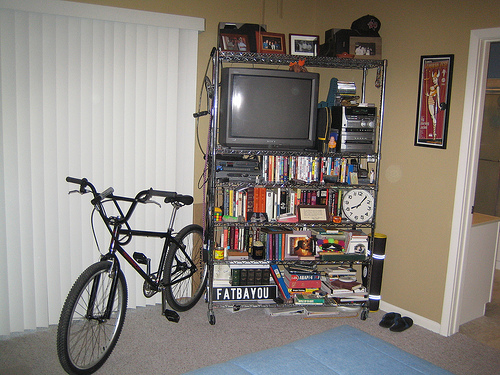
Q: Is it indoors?
A: Yes, it is indoors.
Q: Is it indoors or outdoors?
A: It is indoors.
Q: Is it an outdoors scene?
A: No, it is indoors.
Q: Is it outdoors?
A: No, it is indoors.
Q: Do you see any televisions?
A: Yes, there is a television.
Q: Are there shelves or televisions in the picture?
A: Yes, there is a television.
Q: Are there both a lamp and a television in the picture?
A: No, there is a television but no lamps.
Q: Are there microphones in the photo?
A: No, there are no microphones.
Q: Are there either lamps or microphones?
A: No, there are no microphones or lamps.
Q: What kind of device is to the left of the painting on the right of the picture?
A: The device is a television.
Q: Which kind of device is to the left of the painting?
A: The device is a television.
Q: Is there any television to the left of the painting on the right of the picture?
A: Yes, there is a television to the left of the painting.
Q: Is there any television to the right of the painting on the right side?
A: No, the television is to the left of the painting.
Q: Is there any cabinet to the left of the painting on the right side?
A: No, there is a television to the left of the painting.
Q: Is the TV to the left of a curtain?
A: No, the TV is to the left of the painting.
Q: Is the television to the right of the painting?
A: No, the television is to the left of the painting.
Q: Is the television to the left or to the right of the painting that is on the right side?
A: The television is to the left of the painting.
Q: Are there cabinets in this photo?
A: No, there are no cabinets.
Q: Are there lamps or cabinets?
A: No, there are no cabinets or lamps.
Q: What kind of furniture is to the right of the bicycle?
A: The piece of furniture is a shelf.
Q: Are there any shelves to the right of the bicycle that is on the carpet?
A: Yes, there is a shelf to the right of the bicycle.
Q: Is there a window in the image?
A: Yes, there is a window.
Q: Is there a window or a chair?
A: Yes, there is a window.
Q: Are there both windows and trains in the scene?
A: No, there is a window but no trains.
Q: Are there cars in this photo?
A: No, there are no cars.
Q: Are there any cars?
A: No, there are no cars.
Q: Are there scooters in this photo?
A: No, there are no scooters.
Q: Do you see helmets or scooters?
A: No, there are no scooters or helmets.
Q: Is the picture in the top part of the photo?
A: Yes, the picture is in the top of the image.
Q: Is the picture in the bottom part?
A: No, the picture is in the top of the image.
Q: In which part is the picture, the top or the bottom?
A: The picture is in the top of the image.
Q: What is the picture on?
A: The picture is on the shelf.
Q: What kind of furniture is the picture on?
A: The picture is on the shelf.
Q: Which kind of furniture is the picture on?
A: The picture is on the shelf.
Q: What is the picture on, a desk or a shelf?
A: The picture is on a shelf.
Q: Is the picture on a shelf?
A: Yes, the picture is on a shelf.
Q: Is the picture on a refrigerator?
A: No, the picture is on a shelf.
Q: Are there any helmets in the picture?
A: No, there are no helmets.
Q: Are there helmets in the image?
A: No, there are no helmets.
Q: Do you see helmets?
A: No, there are no helmets.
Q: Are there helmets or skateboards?
A: No, there are no helmets or skateboards.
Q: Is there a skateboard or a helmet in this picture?
A: No, there are no helmets or skateboards.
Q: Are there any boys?
A: No, there are no boys.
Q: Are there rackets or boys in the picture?
A: No, there are no boys or rackets.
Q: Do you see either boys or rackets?
A: No, there are no boys or rackets.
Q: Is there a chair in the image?
A: No, there are no chairs.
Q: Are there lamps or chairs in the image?
A: No, there are no chairs or lamps.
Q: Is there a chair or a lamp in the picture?
A: No, there are no chairs or lamps.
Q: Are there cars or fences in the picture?
A: No, there are no cars or fences.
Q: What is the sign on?
A: The sign is on the shelf.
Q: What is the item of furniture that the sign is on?
A: The piece of furniture is a shelf.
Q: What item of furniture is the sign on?
A: The sign is on the shelf.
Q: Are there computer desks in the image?
A: No, there are no computer desks.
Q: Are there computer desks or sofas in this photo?
A: No, there are no computer desks or sofas.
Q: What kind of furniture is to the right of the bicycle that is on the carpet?
A: The piece of furniture is a shelf.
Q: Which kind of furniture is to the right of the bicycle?
A: The piece of furniture is a shelf.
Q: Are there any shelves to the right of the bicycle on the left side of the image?
A: Yes, there is a shelf to the right of the bicycle.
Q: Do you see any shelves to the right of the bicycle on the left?
A: Yes, there is a shelf to the right of the bicycle.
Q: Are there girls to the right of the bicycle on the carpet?
A: No, there is a shelf to the right of the bicycle.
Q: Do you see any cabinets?
A: No, there are no cabinets.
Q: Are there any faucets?
A: No, there are no faucets.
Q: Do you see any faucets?
A: No, there are no faucets.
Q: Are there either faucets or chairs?
A: No, there are no faucets or chairs.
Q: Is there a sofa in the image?
A: No, there are no sofas.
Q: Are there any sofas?
A: No, there are no sofas.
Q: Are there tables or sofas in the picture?
A: No, there are no sofas or tables.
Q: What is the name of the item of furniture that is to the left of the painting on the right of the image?
A: The piece of furniture is a shelf.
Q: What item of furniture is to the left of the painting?
A: The piece of furniture is a shelf.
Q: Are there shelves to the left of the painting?
A: Yes, there is a shelf to the left of the painting.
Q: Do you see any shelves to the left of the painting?
A: Yes, there is a shelf to the left of the painting.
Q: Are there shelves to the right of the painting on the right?
A: No, the shelf is to the left of the painting.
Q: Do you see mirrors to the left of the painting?
A: No, there is a shelf to the left of the painting.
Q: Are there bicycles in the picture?
A: Yes, there is a bicycle.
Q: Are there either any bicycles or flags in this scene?
A: Yes, there is a bicycle.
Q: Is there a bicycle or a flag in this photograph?
A: Yes, there is a bicycle.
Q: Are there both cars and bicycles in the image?
A: No, there is a bicycle but no cars.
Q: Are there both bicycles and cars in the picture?
A: No, there is a bicycle but no cars.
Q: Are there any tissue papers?
A: No, there are no tissue papers.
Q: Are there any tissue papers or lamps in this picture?
A: No, there are no tissue papers or lamps.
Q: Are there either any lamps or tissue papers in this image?
A: No, there are no tissue papers or lamps.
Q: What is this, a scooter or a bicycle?
A: This is a bicycle.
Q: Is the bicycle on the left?
A: Yes, the bicycle is on the left of the image.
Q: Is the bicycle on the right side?
A: No, the bicycle is on the left of the image.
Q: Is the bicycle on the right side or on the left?
A: The bicycle is on the left of the image.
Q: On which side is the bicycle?
A: The bicycle is on the left of the image.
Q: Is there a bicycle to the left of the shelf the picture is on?
A: Yes, there is a bicycle to the left of the shelf.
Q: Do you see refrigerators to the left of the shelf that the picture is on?
A: No, there is a bicycle to the left of the shelf.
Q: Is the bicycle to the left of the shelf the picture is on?
A: Yes, the bicycle is to the left of the shelf.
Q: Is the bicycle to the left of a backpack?
A: No, the bicycle is to the left of the shelf.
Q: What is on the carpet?
A: The bicycle is on the carpet.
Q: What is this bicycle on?
A: The bicycle is on the carpet.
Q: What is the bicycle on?
A: The bicycle is on the carpet.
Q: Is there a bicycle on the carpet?
A: Yes, there is a bicycle on the carpet.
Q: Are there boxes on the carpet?
A: No, there is a bicycle on the carpet.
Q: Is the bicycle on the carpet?
A: Yes, the bicycle is on the carpet.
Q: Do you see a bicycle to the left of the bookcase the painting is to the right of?
A: Yes, there is a bicycle to the left of the bookcase.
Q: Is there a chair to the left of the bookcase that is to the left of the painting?
A: No, there is a bicycle to the left of the bookcase.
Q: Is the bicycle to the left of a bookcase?
A: Yes, the bicycle is to the left of a bookcase.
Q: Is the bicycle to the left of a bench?
A: No, the bicycle is to the left of a bookcase.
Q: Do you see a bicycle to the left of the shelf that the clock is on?
A: Yes, there is a bicycle to the left of the shelf.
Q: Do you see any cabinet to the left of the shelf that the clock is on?
A: No, there is a bicycle to the left of the shelf.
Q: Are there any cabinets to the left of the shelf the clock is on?
A: No, there is a bicycle to the left of the shelf.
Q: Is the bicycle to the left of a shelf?
A: Yes, the bicycle is to the left of a shelf.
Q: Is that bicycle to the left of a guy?
A: No, the bicycle is to the left of a shelf.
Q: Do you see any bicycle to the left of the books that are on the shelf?
A: Yes, there is a bicycle to the left of the books.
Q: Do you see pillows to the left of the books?
A: No, there is a bicycle to the left of the books.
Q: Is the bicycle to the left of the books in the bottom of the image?
A: Yes, the bicycle is to the left of the books.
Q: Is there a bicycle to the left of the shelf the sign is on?
A: Yes, there is a bicycle to the left of the shelf.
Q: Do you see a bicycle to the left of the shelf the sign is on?
A: Yes, there is a bicycle to the left of the shelf.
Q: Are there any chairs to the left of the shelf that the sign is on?
A: No, there is a bicycle to the left of the shelf.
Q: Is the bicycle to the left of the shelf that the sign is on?
A: Yes, the bicycle is to the left of the shelf.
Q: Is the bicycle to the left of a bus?
A: No, the bicycle is to the left of the shelf.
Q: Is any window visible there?
A: Yes, there is a window.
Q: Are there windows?
A: Yes, there is a window.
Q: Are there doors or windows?
A: Yes, there is a window.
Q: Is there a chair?
A: No, there are no chairs.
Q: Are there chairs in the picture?
A: No, there are no chairs.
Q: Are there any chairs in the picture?
A: No, there are no chairs.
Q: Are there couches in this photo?
A: No, there are no couches.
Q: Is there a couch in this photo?
A: No, there are no couches.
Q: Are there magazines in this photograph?
A: No, there are no magazines.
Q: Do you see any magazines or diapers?
A: No, there are no magazines or diapers.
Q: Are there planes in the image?
A: No, there are no planes.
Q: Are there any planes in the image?
A: No, there are no planes.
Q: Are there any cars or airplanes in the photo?
A: No, there are no airplanes or cars.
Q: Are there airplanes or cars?
A: No, there are no airplanes or cars.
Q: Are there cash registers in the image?
A: No, there are no cash registers.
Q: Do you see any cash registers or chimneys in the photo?
A: No, there are no cash registers or chimneys.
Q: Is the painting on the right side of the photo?
A: Yes, the painting is on the right of the image.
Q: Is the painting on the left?
A: No, the painting is on the right of the image.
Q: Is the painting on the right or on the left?
A: The painting is on the right of the image.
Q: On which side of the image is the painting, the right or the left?
A: The painting is on the right of the image.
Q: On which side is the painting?
A: The painting is on the right of the image.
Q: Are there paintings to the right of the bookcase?
A: Yes, there is a painting to the right of the bookcase.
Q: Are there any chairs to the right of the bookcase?
A: No, there is a painting to the right of the bookcase.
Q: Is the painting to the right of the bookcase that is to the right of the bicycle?
A: Yes, the painting is to the right of the bookcase.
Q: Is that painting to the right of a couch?
A: No, the painting is to the right of the bookcase.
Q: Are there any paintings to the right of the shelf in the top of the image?
A: Yes, there is a painting to the right of the shelf.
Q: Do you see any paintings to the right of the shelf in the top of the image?
A: Yes, there is a painting to the right of the shelf.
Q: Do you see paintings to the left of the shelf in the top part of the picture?
A: No, the painting is to the right of the shelf.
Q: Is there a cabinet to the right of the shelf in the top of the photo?
A: No, there is a painting to the right of the shelf.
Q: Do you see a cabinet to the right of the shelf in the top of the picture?
A: No, there is a painting to the right of the shelf.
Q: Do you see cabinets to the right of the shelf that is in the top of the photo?
A: No, there is a painting to the right of the shelf.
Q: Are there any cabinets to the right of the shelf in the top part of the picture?
A: No, there is a painting to the right of the shelf.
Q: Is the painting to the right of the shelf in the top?
A: Yes, the painting is to the right of the shelf.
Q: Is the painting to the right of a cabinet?
A: No, the painting is to the right of the shelf.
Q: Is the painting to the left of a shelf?
A: No, the painting is to the right of a shelf.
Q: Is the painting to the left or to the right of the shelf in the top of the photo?
A: The painting is to the right of the shelf.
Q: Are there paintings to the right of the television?
A: Yes, there is a painting to the right of the television.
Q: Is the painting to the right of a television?
A: Yes, the painting is to the right of a television.